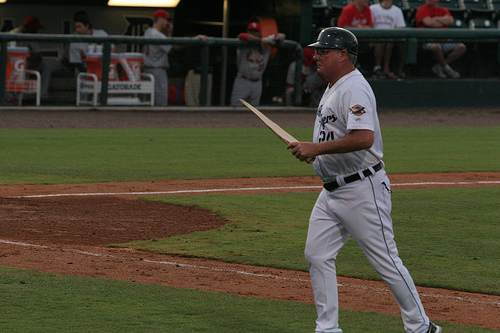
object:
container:
[81, 49, 117, 85]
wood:
[237, 96, 315, 164]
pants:
[305, 160, 431, 333]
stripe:
[367, 174, 427, 327]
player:
[68, 13, 109, 80]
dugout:
[1, 0, 500, 108]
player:
[140, 8, 208, 105]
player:
[0, 14, 51, 105]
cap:
[146, 9, 173, 21]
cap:
[23, 15, 45, 31]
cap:
[248, 22, 261, 31]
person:
[415, 0, 466, 81]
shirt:
[416, 3, 450, 30]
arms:
[423, 16, 439, 25]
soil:
[0, 127, 499, 333]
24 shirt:
[307, 67, 389, 183]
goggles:
[315, 50, 358, 56]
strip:
[11, 180, 324, 200]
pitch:
[0, 127, 499, 332]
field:
[0, 107, 500, 333]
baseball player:
[286, 25, 440, 333]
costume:
[298, 68, 440, 332]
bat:
[233, 95, 314, 163]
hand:
[287, 140, 315, 161]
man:
[280, 25, 446, 332]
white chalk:
[2, 180, 499, 202]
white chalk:
[1, 241, 498, 306]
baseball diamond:
[0, 123, 499, 333]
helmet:
[305, 23, 361, 56]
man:
[143, 10, 177, 105]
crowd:
[449, 0, 498, 80]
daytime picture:
[0, 0, 500, 333]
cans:
[6, 36, 32, 106]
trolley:
[74, 65, 156, 107]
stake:
[234, 100, 313, 166]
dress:
[301, 67, 433, 332]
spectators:
[283, 2, 500, 81]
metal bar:
[0, 32, 302, 107]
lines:
[0, 210, 495, 322]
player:
[229, 22, 286, 106]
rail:
[0, 27, 305, 106]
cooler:
[115, 52, 143, 80]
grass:
[0, 107, 500, 333]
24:
[317, 130, 336, 144]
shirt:
[313, 68, 383, 183]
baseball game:
[2, 0, 499, 332]